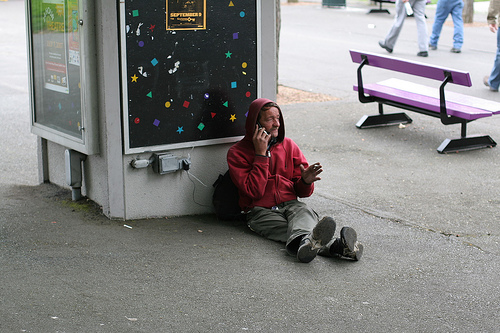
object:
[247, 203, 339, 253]
legs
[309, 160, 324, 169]
cigarette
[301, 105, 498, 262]
street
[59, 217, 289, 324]
street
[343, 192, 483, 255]
crack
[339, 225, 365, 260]
shoe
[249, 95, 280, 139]
head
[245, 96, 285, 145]
hood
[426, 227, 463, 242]
crack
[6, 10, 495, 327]
ground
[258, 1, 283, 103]
pole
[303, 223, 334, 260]
feet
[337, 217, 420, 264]
feet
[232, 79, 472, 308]
man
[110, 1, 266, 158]
post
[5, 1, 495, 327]
floor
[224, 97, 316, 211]
hoodie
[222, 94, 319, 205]
red hoodie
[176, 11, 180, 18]
letter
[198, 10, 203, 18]
letter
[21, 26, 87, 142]
post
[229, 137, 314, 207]
jacket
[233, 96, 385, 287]
man ground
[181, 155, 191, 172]
outlet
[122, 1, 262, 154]
poster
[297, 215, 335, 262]
shoe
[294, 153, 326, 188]
left hand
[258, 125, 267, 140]
cellphone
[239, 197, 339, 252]
pants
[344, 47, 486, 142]
bench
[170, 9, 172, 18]
letter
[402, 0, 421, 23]
bottle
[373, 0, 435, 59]
man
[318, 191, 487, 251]
line